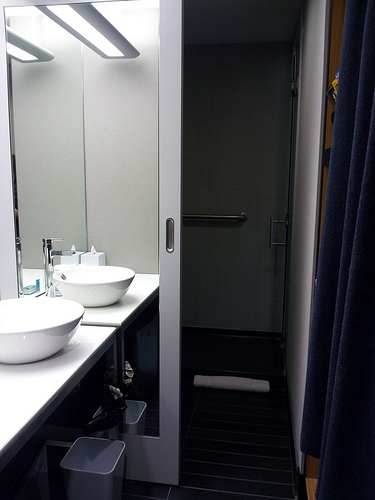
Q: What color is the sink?
A: White.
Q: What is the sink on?
A: Counter.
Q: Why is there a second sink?
A: Reflection.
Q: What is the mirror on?
A: Door.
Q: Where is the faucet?
A: Behind sink.